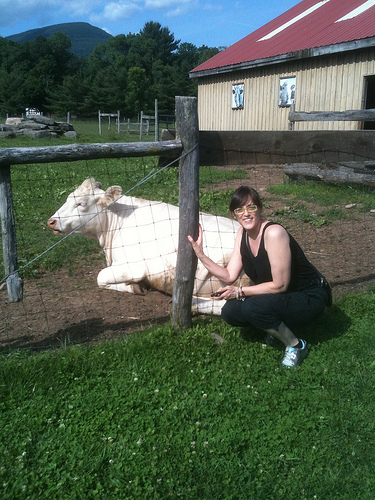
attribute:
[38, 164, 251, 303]
cow — white, lying, laying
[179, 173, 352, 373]
woman — stooping, leaning, smiling, posing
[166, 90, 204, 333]
post — gray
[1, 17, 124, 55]
mountain — small, green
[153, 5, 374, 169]
barn — red-roofed, brown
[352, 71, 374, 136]
door — open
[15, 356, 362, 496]
grass — green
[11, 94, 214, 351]
fence — brown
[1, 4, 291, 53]
sky — cloudy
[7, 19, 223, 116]
trees — green, tall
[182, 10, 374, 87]
roof — red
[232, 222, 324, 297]
tank top — black, sleeveless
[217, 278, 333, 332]
pants — black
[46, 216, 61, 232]
nose — pink